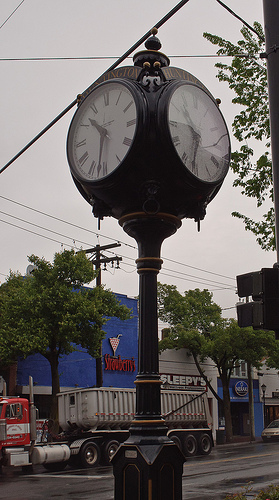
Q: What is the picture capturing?
A: A street clock.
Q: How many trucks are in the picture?
A: One.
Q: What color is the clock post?
A: Black.